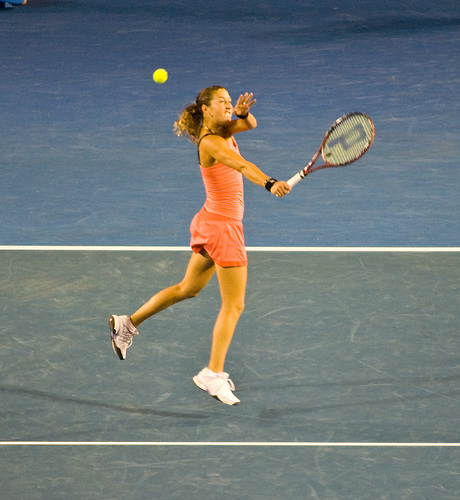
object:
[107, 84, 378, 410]
woman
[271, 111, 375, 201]
racket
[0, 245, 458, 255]
line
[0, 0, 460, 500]
court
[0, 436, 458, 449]
line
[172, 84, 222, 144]
hair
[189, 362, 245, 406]
foot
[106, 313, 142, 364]
foot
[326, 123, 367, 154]
letter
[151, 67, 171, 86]
ball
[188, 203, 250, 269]
shorts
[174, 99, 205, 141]
pony tail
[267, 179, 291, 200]
hand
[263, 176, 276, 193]
band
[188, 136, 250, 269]
outfit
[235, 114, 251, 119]
band